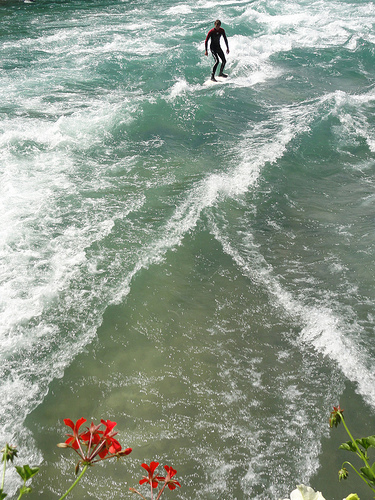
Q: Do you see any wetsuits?
A: Yes, there is a wetsuit.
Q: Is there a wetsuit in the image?
A: Yes, there is a wetsuit.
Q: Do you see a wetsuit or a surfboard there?
A: Yes, there is a wetsuit.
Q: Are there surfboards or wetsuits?
A: Yes, there is a wetsuit.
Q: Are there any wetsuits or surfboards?
A: Yes, there is a wetsuit.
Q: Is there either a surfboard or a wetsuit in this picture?
A: Yes, there is a wetsuit.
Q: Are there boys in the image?
A: No, there are no boys.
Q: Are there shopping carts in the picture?
A: No, there are no shopping carts.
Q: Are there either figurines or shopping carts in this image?
A: No, there are no shopping carts or figurines.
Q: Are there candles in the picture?
A: No, there are no candles.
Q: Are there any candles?
A: No, there are no candles.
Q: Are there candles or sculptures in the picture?
A: No, there are no candles or sculptures.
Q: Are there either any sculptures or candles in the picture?
A: No, there are no candles or sculptures.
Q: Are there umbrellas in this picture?
A: No, there are no umbrellas.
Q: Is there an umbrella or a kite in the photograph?
A: No, there are no umbrellas or kites.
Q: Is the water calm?
A: Yes, the water is calm.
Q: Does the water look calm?
A: Yes, the water is calm.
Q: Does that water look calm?
A: Yes, the water is calm.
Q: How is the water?
A: The water is calm.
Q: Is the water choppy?
A: No, the water is calm.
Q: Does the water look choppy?
A: No, the water is calm.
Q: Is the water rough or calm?
A: The water is calm.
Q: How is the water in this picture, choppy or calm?
A: The water is calm.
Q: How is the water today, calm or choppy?
A: The water is calm.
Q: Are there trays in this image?
A: No, there are no trays.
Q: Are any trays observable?
A: No, there are no trays.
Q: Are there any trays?
A: No, there are no trays.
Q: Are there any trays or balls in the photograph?
A: No, there are no trays or balls.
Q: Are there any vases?
A: No, there are no vases.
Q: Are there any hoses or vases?
A: No, there are no vases or hoses.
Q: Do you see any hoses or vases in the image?
A: No, there are no vases or hoses.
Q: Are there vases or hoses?
A: No, there are no vases or hoses.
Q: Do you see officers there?
A: No, there are no officers.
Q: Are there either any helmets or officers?
A: No, there are no officers or helmets.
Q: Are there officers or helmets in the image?
A: No, there are no officers or helmets.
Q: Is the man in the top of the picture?
A: Yes, the man is in the top of the image.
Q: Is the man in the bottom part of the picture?
A: No, the man is in the top of the image.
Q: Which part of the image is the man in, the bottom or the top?
A: The man is in the top of the image.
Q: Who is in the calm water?
A: The man is in the water.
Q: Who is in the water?
A: The man is in the water.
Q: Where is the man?
A: The man is in the water.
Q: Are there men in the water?
A: Yes, there is a man in the water.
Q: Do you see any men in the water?
A: Yes, there is a man in the water.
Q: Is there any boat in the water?
A: No, there is a man in the water.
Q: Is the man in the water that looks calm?
A: Yes, the man is in the water.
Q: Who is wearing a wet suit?
A: The man is wearing a wet suit.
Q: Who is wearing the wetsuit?
A: The man is wearing a wet suit.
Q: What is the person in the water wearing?
A: The man is wearing a wet suit.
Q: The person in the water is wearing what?
A: The man is wearing a wet suit.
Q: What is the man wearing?
A: The man is wearing a wet suit.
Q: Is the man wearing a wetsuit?
A: Yes, the man is wearing a wetsuit.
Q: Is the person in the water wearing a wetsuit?
A: Yes, the man is wearing a wetsuit.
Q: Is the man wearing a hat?
A: No, the man is wearing a wetsuit.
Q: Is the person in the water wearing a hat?
A: No, the man is wearing a wetsuit.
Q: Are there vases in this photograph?
A: No, there are no vases.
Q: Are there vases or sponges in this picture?
A: No, there are no vases or sponges.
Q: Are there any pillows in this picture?
A: No, there are no pillows.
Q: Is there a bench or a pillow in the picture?
A: No, there are no pillows or benches.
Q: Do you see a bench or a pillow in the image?
A: No, there are no pillows or benches.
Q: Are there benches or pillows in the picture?
A: No, there are no pillows or benches.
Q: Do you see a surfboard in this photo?
A: Yes, there is a surfboard.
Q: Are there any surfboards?
A: Yes, there is a surfboard.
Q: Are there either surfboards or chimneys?
A: Yes, there is a surfboard.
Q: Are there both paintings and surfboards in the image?
A: No, there is a surfboard but no paintings.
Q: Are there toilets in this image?
A: No, there are no toilets.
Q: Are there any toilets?
A: No, there are no toilets.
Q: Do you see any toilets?
A: No, there are no toilets.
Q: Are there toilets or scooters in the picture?
A: No, there are no toilets or scooters.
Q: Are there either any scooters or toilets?
A: No, there are no toilets or scooters.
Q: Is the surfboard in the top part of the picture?
A: Yes, the surfboard is in the top of the image.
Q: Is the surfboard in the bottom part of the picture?
A: No, the surfboard is in the top of the image.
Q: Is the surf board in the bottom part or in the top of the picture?
A: The surf board is in the top of the image.